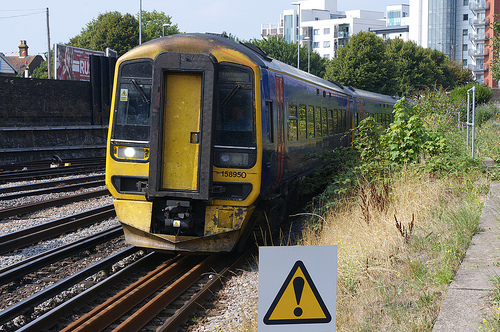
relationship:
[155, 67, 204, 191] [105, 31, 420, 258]
door of train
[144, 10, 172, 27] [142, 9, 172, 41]
leaves on tree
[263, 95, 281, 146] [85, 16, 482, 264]
window of train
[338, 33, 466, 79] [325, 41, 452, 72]
leaves on tree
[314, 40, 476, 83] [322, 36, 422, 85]
leaves on tree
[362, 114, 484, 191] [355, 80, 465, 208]
leaves on tree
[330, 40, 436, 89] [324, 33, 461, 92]
leaves on tree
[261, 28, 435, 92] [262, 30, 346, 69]
leaves on tree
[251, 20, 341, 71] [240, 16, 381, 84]
leaves on tree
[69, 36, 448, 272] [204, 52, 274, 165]
train has a window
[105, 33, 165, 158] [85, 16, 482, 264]
window on a train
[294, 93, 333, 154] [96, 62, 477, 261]
window in train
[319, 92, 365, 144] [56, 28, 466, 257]
window in train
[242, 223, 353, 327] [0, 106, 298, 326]
sign by tracks